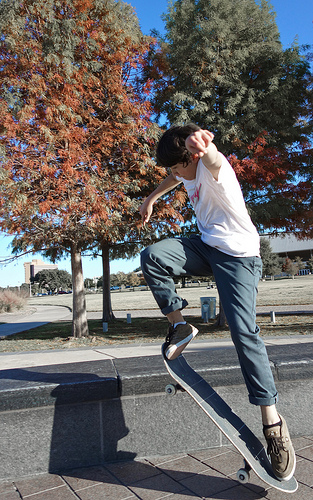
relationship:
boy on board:
[127, 111, 292, 417] [154, 346, 299, 495]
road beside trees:
[4, 334, 312, 468] [1, 2, 312, 260]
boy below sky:
[127, 111, 292, 417] [0, 2, 312, 81]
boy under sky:
[127, 111, 292, 417] [0, 2, 312, 81]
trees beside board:
[1, 2, 312, 260] [154, 346, 299, 495]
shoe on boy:
[157, 318, 195, 359] [127, 111, 292, 417]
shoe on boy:
[256, 408, 296, 477] [127, 111, 292, 417]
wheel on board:
[162, 382, 180, 402] [146, 328, 303, 491]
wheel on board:
[230, 463, 253, 481] [146, 328, 303, 491]